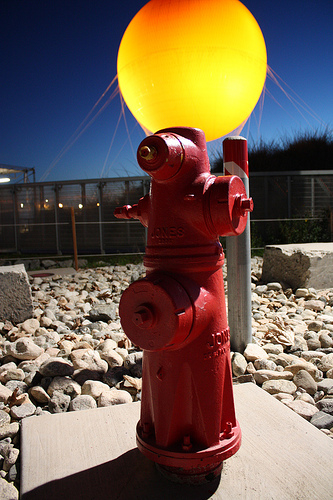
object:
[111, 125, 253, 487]
fire hydrant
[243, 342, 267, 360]
rock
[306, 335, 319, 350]
rock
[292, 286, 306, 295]
rock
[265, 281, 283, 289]
rock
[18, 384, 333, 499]
base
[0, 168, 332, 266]
fence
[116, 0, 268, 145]
balloon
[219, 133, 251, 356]
pole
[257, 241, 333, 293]
bricks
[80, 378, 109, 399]
stones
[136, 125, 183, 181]
top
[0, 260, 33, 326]
stone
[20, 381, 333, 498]
slab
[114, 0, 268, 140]
baloon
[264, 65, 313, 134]
rope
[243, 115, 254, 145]
rope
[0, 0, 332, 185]
sky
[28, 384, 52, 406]
rocks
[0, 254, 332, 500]
ground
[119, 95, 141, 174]
line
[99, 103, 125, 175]
line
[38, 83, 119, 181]
line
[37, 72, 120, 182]
line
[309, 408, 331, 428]
stones